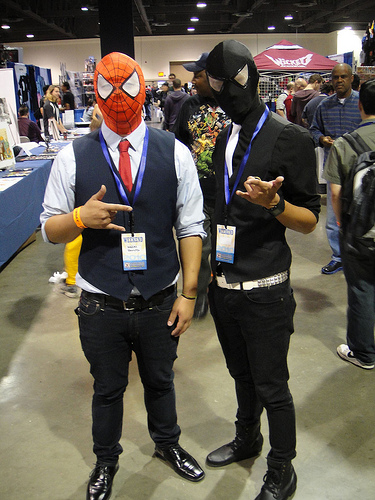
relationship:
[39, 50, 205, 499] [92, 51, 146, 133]
man wearing mask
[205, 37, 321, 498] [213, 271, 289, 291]
man wearing belt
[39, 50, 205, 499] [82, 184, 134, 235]
man gesturing with hand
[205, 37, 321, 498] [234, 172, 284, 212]
man gesturing with hand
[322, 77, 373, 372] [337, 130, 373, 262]
man has backpack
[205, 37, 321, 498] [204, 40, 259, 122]
man wearing mask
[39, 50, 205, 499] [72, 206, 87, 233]
man has wristband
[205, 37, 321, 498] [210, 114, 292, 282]
man wearing vest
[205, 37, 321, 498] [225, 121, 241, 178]
man has tie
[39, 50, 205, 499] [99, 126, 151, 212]
man has lanyard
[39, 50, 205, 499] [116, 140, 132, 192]
man has tie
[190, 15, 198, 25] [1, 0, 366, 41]
light on ceiling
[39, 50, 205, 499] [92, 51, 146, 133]
man has mask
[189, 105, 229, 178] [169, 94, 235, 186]
design on shirt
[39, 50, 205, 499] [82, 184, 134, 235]
man has hand